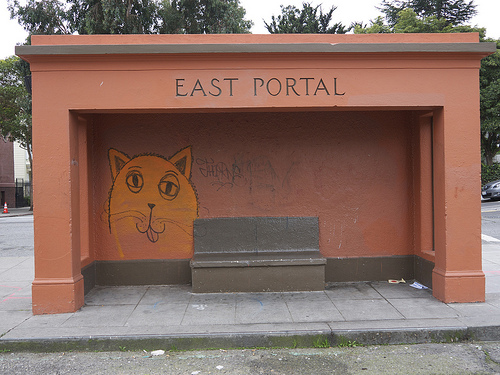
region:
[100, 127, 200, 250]
A cartoon on the wall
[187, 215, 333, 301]
A cemented grey seat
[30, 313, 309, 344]
A cemented pavement road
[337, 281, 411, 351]
A cemented pavement road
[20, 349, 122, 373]
A cemented pavement road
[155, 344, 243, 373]
A cemented pavement road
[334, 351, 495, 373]
A cemented pavement road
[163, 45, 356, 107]
writting on the stage shade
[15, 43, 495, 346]
An orange stage shade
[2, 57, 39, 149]
A green tree branch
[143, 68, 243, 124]
gray letters that spell east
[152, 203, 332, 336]
gray bench under ease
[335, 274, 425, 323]
litter on th ground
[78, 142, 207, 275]
cat painted on wall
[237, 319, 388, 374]
green grass in cracks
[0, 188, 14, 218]
orange and white cone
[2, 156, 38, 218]
shadows on the building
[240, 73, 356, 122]
gray letters that spell portal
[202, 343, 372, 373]
oil stain on concrete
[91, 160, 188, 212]
two cats eyes painted on wall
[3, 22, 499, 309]
outdoor resting area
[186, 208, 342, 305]
bench inside resting area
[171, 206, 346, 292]
bench is made of stone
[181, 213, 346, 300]
bench is painted brown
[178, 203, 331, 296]
bench seats two people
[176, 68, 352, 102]
words East Portal painted on building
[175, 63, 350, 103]
letters are black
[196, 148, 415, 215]
graffiti on building wall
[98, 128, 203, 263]
cat drawn inside of building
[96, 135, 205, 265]
cat is yellow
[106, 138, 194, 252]
The cat is orange.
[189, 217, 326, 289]
The bench is brown.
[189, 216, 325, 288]
The bench is concrete.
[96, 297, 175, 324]
The pavement is brown.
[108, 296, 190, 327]
The pavement is concrete.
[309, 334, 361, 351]
The grass by the curb is green.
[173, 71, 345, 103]
The words on the building are in English.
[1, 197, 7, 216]
The cone in the background is white and orange.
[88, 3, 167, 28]
The trees above the building are green.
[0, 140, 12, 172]
The building in the background is brown.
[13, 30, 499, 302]
Shelter area for waiting patrons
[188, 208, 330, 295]
Bench for waiting paatrons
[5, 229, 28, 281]
Part of sidewalk behind shelter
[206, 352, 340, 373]
Part of street in front of shelter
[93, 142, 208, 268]
Part of graffitti on shelter wall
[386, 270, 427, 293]
Litter left inside shelter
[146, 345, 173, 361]
litter left on street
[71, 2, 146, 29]
Part of green tree behind shelter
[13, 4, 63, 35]
Part of green tree behind shelter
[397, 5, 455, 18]
Part of green tree behind shelter